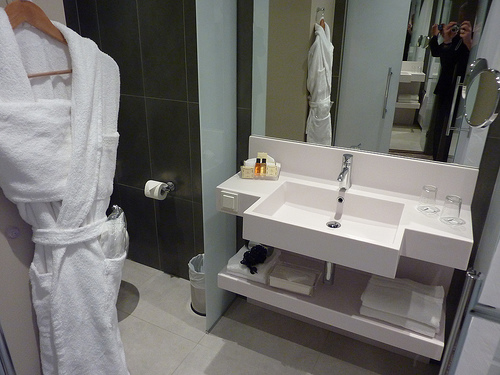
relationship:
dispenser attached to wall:
[157, 178, 177, 195] [61, 0, 211, 282]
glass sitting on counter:
[417, 184, 438, 214] [221, 164, 477, 249]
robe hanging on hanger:
[6, 29, 179, 366] [0, 1, 74, 78]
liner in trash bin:
[187, 255, 204, 291] [186, 253, 209, 316]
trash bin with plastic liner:
[179, 251, 211, 323] [184, 250, 207, 290]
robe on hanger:
[1, 77, 121, 372] [7, 4, 62, 40]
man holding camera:
[422, 2, 478, 162] [450, 21, 460, 33]